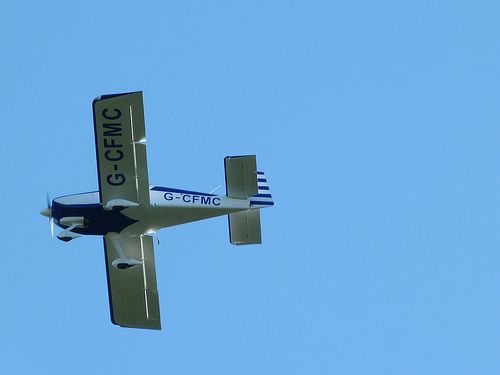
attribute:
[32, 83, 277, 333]
plane — blue and white stripes, tail , right wheel ,  vertical stabilizer 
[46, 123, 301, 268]
plane — landing gear 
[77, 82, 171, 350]
plane — lwing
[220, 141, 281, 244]
plane — back wing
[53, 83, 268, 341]
plane — blue and white stripes, front wheel, propeller 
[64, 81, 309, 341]
plane — blue and white stripes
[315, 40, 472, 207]
sky — cloudless blue color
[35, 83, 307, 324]
plane — blue and white stripes, white propeller 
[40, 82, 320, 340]
plane — green , thin white pole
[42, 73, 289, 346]
plane — side wings, small blue design, left wheel 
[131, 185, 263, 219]
plane — bottom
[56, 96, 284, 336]
plane — left wing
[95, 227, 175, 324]
plane — right wing 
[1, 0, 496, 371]
sky — blue